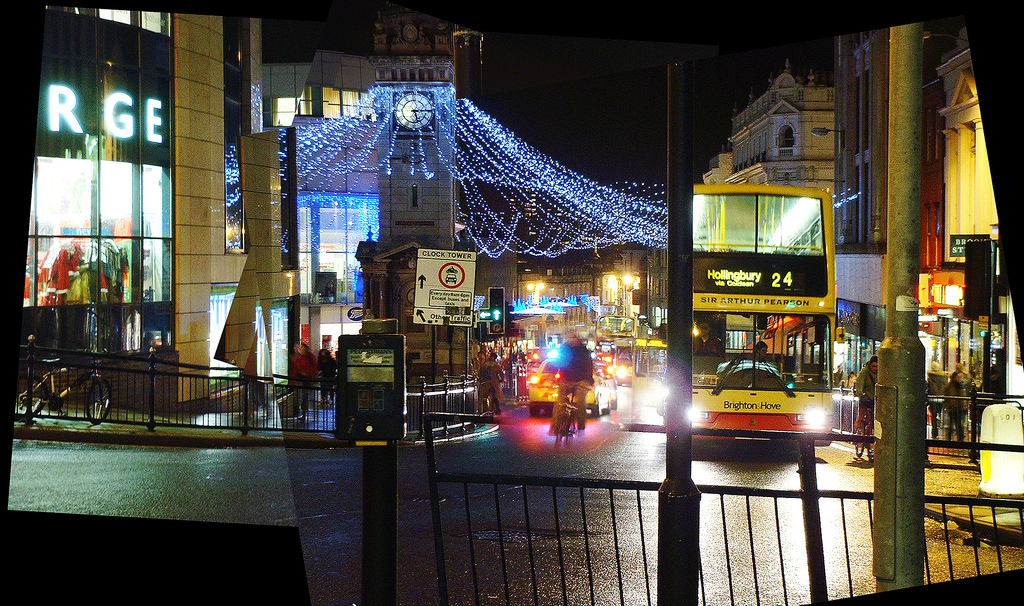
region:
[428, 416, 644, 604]
A black gate on the street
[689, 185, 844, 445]
The front of a double decker bus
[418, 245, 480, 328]
A white and red street sign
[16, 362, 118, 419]
A bicycle behind a gate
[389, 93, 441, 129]
A clock on top of a building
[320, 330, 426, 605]
A parking meter next to a gate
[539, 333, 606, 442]
A person riding a bike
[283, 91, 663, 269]
A large string of lights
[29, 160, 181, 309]
A store window with items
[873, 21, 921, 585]
A large metal pole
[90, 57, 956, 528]
this is a city area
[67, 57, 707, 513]
this area is lit up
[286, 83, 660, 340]
the lights are hanging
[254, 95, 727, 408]
the lights are blue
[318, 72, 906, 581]
this is a public bus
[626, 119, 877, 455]
the bus is yellow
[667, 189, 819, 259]
the windows are glowing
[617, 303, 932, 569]
the headlights are on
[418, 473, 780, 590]
the fence is short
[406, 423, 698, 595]
the fence is black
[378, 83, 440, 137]
clock on the tower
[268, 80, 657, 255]
blue lights over the street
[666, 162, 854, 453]
the bus on the street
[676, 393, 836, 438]
headlights of the bus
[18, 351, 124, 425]
bicycle on the fence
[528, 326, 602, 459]
person riding the bicycle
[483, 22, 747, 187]
the black night sky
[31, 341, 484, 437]
the black fence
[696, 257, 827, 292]
the led sign on the bus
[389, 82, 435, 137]
White and black clockface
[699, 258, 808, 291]
Yellow words and number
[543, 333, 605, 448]
Person riding a bicycle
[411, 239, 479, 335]
Red, white, and black street sign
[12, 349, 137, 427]
Parked yellow and black bike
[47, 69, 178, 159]
The letters R G and E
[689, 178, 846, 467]
A large yellow and black bus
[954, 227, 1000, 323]
An all black traffic light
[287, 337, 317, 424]
A woman with red shirt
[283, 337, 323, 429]
A woman walking on sidewalk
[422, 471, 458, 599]
black bar of fence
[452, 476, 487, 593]
black bar of fence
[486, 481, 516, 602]
black bar of fence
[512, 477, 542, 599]
black bar of fence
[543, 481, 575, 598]
black bar of fence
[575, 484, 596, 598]
black bar of fence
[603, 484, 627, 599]
black bar of fence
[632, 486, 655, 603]
black bar of fence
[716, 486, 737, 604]
black bar of fence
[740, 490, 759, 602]
black bar of fence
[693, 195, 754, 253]
glass is clear and clean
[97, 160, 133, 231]
glass is clear and clean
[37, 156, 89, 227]
glass is clear and clean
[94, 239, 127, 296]
glass is clear and clean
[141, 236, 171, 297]
glass is clear and clean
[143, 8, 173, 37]
glass is clear and clean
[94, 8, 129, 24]
glass is clear and clean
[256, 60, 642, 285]
blue lights above ground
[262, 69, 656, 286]
lights near the building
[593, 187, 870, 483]
front of the bus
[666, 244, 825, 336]
number and words on bus